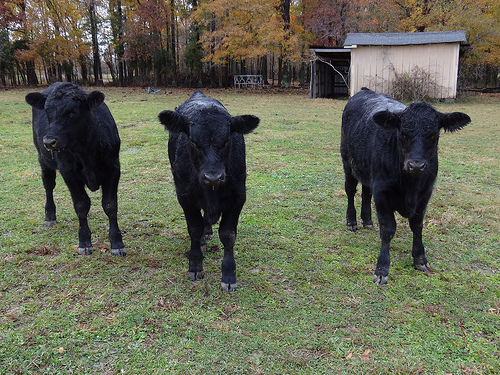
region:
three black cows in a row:
[26, 50, 468, 335]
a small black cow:
[313, 75, 483, 310]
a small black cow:
[138, 58, 303, 329]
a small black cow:
[21, 66, 145, 282]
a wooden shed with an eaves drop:
[293, 33, 499, 149]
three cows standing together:
[12, 63, 474, 334]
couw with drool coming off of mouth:
[15, 68, 162, 272]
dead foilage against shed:
[367, 52, 465, 131]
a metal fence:
[235, 60, 293, 117]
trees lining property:
[33, 5, 480, 117]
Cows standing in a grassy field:
[6, 44, 449, 302]